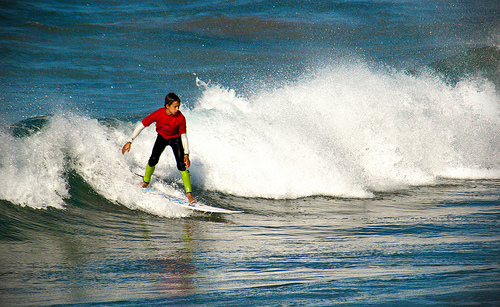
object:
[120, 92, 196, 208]
boy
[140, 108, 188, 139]
red shirt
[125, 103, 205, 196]
suit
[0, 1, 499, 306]
blue water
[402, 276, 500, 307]
blue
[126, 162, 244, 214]
surfboard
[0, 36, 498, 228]
wave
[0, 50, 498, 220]
white cap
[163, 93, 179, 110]
hair